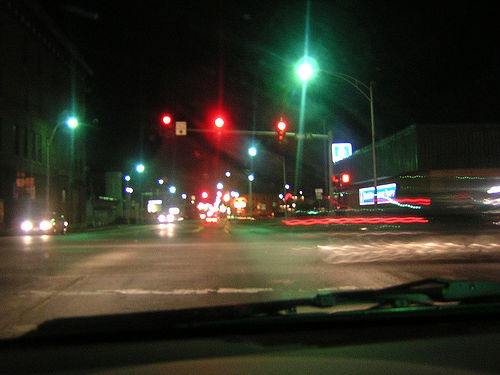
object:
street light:
[135, 165, 147, 173]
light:
[272, 117, 291, 140]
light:
[212, 112, 226, 142]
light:
[202, 191, 209, 197]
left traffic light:
[158, 112, 175, 129]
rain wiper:
[16, 274, 499, 344]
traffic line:
[25, 285, 378, 297]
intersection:
[1, 234, 427, 339]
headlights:
[19, 220, 33, 231]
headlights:
[157, 217, 165, 222]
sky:
[38, 0, 498, 167]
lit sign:
[331, 142, 354, 160]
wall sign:
[357, 182, 396, 205]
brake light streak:
[280, 214, 429, 223]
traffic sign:
[175, 123, 187, 135]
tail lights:
[203, 216, 219, 225]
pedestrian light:
[341, 172, 351, 185]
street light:
[292, 55, 322, 86]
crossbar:
[179, 130, 184, 134]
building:
[332, 121, 500, 213]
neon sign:
[232, 196, 248, 210]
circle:
[162, 116, 172, 124]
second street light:
[246, 144, 259, 157]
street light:
[65, 115, 79, 130]